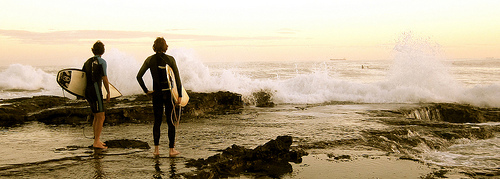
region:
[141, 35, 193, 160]
a surfer standing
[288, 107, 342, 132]
water on the sand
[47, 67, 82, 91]
a surfboard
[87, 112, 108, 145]
a mans leg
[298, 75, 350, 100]
the water is white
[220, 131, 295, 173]
a rock on the beach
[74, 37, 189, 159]
two men standing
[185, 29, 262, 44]
clouds in the sky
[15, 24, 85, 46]
the clouds are white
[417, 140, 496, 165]
the water is white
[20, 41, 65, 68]
white clouds in blue sky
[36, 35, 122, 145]
surfer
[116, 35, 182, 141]
surfer carrying board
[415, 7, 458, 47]
white clouds in blue sky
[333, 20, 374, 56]
white clouds in blue sky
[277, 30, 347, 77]
white clouds in blue sky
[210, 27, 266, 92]
white clouds in blue sky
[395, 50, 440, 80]
white clouds in blue sky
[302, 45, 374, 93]
white clouds in blue sky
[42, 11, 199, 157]
two people watching the waves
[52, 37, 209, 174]
men carrying the surfboards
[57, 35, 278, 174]
People on the beach.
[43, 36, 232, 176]
Men on the beach.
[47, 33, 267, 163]
Men holding surfboards.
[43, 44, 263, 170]
Men in wet suits.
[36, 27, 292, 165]
men on the beach with boards.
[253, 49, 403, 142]
Waves in the water.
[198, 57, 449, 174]
Wave on the shore.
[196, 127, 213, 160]
Rock on the beach.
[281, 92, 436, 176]
Ripples in the wave.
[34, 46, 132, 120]
White surfboard with the man.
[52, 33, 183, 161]
Two people with surfboards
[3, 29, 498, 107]
Water splashing on the shore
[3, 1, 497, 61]
Orange cloudy distant sky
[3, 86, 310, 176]
Large rocks on the shore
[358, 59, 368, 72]
Tiny object in the distant water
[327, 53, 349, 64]
Long object in the distance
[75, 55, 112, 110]
Dark sports gear with light patches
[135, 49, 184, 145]
Dark sporting gear covering upto the calf muscles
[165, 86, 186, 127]
Cable hanging from the surfboard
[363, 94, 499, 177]
Depresion on the ground